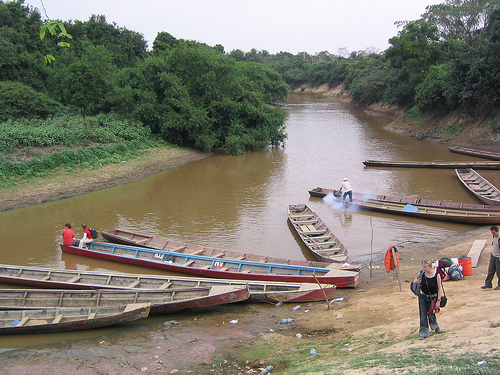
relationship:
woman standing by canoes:
[407, 257, 461, 344] [70, 253, 328, 320]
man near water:
[486, 227, 499, 274] [228, 101, 411, 229]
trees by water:
[189, 72, 287, 153] [228, 101, 411, 229]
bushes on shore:
[35, 127, 146, 158] [61, 139, 202, 189]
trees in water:
[189, 72, 287, 156] [228, 101, 411, 229]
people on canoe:
[63, 215, 94, 255] [73, 256, 271, 277]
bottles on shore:
[202, 310, 314, 330] [103, 283, 369, 356]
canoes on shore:
[70, 253, 328, 320] [103, 283, 369, 356]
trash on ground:
[178, 321, 281, 374] [261, 327, 398, 373]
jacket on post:
[386, 250, 406, 275] [394, 253, 402, 287]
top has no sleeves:
[418, 273, 449, 301] [436, 273, 444, 304]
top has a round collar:
[418, 273, 449, 301] [423, 274, 439, 280]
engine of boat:
[336, 187, 340, 202] [319, 181, 474, 213]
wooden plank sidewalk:
[474, 242, 483, 263] [472, 242, 483, 258]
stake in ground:
[369, 242, 382, 281] [198, 226, 499, 374]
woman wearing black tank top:
[407, 257, 461, 344] [421, 273, 438, 294]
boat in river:
[319, 181, 474, 213] [298, 91, 386, 174]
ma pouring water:
[326, 186, 354, 215] [335, 204, 341, 210]